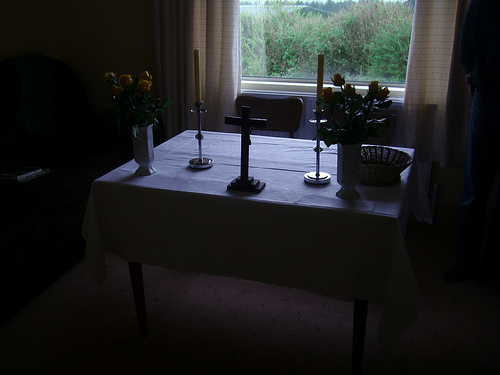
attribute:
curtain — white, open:
[160, 0, 243, 135]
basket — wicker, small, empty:
[357, 146, 411, 189]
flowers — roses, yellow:
[97, 70, 164, 128]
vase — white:
[131, 126, 166, 179]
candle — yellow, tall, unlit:
[191, 47, 204, 101]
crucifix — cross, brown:
[219, 103, 270, 197]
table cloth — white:
[78, 125, 427, 337]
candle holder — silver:
[190, 102, 214, 170]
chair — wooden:
[232, 91, 301, 139]